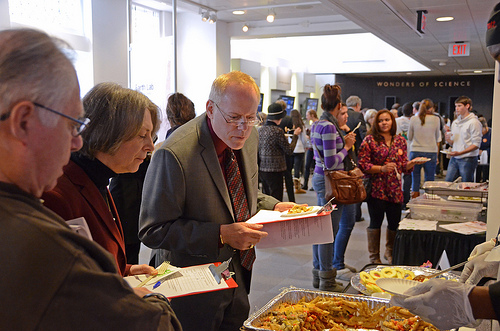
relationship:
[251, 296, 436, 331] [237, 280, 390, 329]
food on tray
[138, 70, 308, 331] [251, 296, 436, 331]
guy looking at food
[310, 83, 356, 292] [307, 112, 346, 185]
people wearing sweater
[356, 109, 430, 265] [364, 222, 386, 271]
person wearing boot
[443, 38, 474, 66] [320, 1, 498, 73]
exit on ceiling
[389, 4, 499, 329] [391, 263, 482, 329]
man wearing glove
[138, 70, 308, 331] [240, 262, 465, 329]
guy looking at buffet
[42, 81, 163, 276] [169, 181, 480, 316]
lady looking at buffett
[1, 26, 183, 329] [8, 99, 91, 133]
man wearing glasses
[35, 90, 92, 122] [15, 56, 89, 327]
glasses on man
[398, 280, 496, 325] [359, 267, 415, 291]
hand serving circles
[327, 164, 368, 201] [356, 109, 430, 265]
brown bag being carried by person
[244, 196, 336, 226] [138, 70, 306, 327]
clip board being carried by man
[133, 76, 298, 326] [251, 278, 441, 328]
guy looking at food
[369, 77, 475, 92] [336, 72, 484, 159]
sign on wall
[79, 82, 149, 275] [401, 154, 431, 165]
lady holding plate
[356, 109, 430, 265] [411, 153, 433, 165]
person holding food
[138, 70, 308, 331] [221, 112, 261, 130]
guy wearing eyeglasses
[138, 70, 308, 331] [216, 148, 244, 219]
guy wearing tie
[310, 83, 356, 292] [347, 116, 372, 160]
people holding spoon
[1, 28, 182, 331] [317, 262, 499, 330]
man standing next to table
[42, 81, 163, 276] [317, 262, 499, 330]
lady standing next to table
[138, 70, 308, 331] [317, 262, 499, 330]
guy standing next to table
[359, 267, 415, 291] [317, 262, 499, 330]
circles on table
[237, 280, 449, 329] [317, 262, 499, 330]
food on table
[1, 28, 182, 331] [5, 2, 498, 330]
man standing in room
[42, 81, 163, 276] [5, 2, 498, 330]
lady standing in room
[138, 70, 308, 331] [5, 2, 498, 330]
guy standing in room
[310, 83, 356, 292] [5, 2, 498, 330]
people standing in room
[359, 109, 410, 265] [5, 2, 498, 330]
person standing in room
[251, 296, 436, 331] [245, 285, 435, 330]
food in tray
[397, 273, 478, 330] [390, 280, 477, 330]
glove on hand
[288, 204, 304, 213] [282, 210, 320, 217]
food on plate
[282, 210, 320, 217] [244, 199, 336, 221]
plate on clipboard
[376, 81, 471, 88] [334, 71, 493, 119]
sign on wall